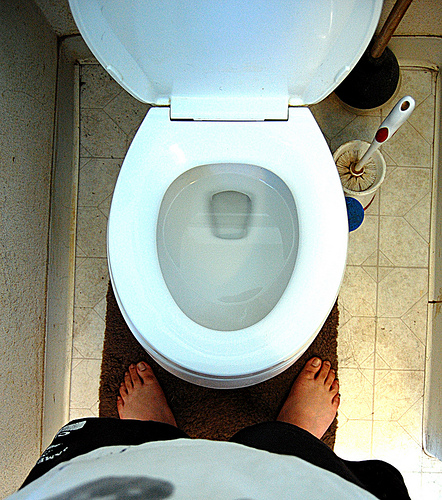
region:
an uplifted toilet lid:
[68, 0, 383, 111]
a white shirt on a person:
[3, 437, 379, 498]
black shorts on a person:
[13, 415, 412, 498]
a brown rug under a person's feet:
[98, 279, 350, 451]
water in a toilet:
[162, 170, 294, 305]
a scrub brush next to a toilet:
[338, 94, 414, 181]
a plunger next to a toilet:
[335, 0, 413, 112]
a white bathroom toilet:
[68, 0, 385, 390]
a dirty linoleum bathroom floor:
[68, 64, 433, 498]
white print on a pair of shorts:
[35, 416, 85, 466]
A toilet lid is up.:
[63, 1, 388, 122]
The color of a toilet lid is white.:
[63, 0, 388, 125]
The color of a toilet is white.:
[65, 1, 383, 395]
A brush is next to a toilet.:
[327, 92, 417, 213]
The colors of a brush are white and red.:
[331, 90, 419, 197]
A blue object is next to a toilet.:
[341, 193, 363, 232]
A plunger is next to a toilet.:
[330, 1, 414, 114]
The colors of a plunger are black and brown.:
[330, 1, 415, 115]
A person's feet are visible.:
[109, 353, 340, 440]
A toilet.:
[64, 0, 385, 383]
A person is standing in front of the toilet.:
[13, 360, 415, 498]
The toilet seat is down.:
[99, 98, 356, 392]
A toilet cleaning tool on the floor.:
[339, 95, 417, 199]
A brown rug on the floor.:
[85, 277, 352, 465]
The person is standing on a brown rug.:
[22, 305, 407, 498]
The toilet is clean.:
[96, 103, 352, 389]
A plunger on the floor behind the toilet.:
[340, 0, 423, 112]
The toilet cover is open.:
[66, 2, 381, 133]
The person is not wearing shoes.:
[28, 352, 415, 496]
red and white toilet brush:
[330, 93, 423, 193]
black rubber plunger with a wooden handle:
[333, 1, 413, 115]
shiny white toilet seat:
[96, 101, 353, 383]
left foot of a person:
[111, 356, 179, 427]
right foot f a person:
[275, 351, 345, 441]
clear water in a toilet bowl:
[156, 166, 299, 309]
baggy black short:
[12, 412, 420, 497]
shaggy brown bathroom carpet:
[90, 267, 344, 450]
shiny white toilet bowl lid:
[59, 0, 396, 128]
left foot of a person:
[110, 357, 185, 430]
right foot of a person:
[279, 350, 345, 441]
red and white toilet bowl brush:
[332, 88, 422, 230]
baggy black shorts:
[13, 410, 412, 498]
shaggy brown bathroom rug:
[95, 267, 345, 465]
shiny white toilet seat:
[95, 105, 352, 388]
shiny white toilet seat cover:
[60, 1, 383, 119]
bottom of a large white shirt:
[5, 434, 388, 498]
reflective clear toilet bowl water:
[151, 166, 301, 311]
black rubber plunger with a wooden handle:
[333, 1, 406, 120]